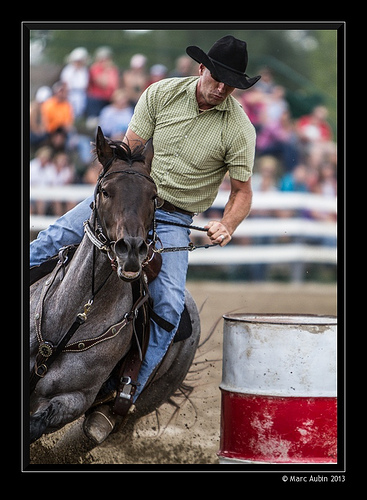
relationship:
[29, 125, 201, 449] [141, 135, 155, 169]
horse has ear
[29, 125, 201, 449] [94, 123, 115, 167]
horse has ear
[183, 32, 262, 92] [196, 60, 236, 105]
hat on top of head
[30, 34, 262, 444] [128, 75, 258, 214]
man wearing shirt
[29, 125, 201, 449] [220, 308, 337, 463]
horse racing around drum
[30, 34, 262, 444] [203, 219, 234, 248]
man has hand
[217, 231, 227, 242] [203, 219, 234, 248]
ring worn on hand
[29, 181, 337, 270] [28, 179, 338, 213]
fence has rail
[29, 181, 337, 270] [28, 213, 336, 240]
fence has rail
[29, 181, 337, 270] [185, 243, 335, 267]
fence has rail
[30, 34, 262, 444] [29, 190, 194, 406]
man wearing jeans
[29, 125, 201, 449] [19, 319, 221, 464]
horse kicking up dirt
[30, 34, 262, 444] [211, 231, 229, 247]
man has finger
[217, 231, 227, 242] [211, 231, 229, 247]
ring around finger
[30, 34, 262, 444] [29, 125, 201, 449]
man riding on horse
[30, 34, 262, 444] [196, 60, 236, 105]
man has head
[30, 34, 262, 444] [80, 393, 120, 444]
man wearing boot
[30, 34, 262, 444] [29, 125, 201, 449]
man leaning on horse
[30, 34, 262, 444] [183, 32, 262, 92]
man wearing hat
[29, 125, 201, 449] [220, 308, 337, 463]
horse running around drum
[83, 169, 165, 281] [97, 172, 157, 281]
straps around horse face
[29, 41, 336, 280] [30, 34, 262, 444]
spectators watching man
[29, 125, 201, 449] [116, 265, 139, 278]
horse has mouth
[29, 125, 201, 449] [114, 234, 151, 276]
horse has nose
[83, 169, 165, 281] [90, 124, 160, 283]
straps around horse head